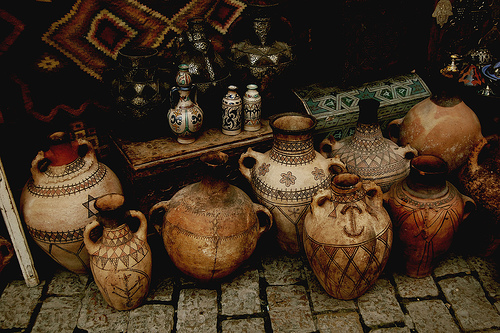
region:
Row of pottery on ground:
[38, 75, 478, 286]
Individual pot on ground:
[90, 192, 161, 309]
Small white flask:
[221, 83, 246, 131]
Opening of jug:
[50, 128, 67, 141]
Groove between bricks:
[258, 289, 275, 331]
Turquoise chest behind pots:
[293, 79, 429, 124]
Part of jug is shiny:
[246, 47, 289, 80]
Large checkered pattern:
[61, 12, 168, 63]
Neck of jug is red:
[43, 132, 85, 175]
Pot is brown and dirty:
[185, 163, 267, 275]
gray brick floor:
[159, 283, 289, 331]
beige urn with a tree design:
[80, 191, 156, 317]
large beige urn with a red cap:
[17, 124, 128, 285]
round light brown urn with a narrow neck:
[147, 151, 274, 295]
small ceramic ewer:
[160, 84, 212, 150]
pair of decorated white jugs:
[217, 78, 263, 138]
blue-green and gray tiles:
[295, 71, 426, 116]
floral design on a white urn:
[252, 150, 329, 192]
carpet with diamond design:
[5, 2, 258, 89]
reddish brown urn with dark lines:
[384, 149, 474, 284]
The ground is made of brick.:
[215, 270, 499, 331]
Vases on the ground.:
[43, 62, 495, 300]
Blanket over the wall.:
[0, 2, 312, 85]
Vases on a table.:
[160, 54, 297, 139]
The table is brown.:
[125, 139, 265, 171]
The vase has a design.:
[86, 215, 154, 313]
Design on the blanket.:
[43, 1, 248, 95]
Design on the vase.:
[296, 197, 386, 297]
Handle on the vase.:
[228, 146, 270, 178]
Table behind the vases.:
[291, 71, 428, 138]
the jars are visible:
[220, 143, 342, 270]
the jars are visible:
[164, 136, 372, 313]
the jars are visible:
[268, 241, 333, 293]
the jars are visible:
[145, 104, 305, 265]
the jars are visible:
[134, 56, 418, 316]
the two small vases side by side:
[220, 81, 257, 131]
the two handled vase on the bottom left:
[84, 187, 154, 314]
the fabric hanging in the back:
[12, 13, 180, 113]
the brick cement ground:
[192, 290, 315, 331]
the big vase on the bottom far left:
[17, 127, 118, 275]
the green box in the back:
[300, 67, 430, 143]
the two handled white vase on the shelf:
[163, 60, 204, 145]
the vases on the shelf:
[97, 28, 291, 139]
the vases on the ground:
[25, 120, 497, 306]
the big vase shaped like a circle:
[150, 150, 274, 274]